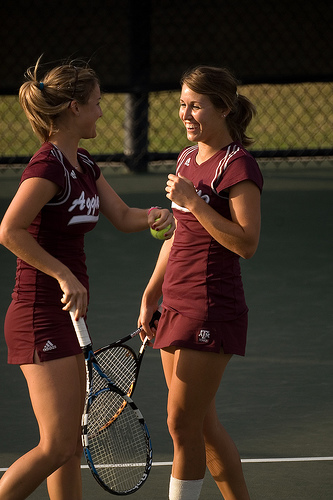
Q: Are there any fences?
A: Yes, there is a fence.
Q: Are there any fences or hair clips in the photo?
A: Yes, there is a fence.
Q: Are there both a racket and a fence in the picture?
A: Yes, there are both a fence and a racket.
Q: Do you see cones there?
A: No, there are no cones.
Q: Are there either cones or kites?
A: No, there are no cones or kites.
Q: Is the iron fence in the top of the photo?
A: Yes, the fence is in the top of the image.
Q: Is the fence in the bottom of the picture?
A: No, the fence is in the top of the image.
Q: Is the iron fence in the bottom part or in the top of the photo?
A: The fence is in the top of the image.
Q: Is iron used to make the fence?
A: Yes, the fence is made of iron.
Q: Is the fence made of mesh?
A: No, the fence is made of iron.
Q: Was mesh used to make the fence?
A: No, the fence is made of iron.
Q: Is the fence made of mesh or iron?
A: The fence is made of iron.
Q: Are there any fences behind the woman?
A: Yes, there is a fence behind the woman.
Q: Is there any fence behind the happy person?
A: Yes, there is a fence behind the woman.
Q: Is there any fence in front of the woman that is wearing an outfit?
A: No, the fence is behind the woman.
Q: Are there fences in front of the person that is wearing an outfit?
A: No, the fence is behind the woman.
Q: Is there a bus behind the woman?
A: No, there is a fence behind the woman.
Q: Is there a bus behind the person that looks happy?
A: No, there is a fence behind the woman.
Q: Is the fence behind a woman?
A: Yes, the fence is behind a woman.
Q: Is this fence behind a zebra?
A: No, the fence is behind a woman.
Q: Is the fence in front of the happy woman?
A: No, the fence is behind the woman.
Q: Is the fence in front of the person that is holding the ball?
A: No, the fence is behind the woman.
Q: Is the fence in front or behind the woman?
A: The fence is behind the woman.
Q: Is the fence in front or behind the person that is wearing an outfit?
A: The fence is behind the woman.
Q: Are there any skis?
A: No, there are no skis.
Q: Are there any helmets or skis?
A: No, there are no skis or helmets.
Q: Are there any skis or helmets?
A: No, there are no skis or helmets.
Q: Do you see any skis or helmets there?
A: No, there are no skis or helmets.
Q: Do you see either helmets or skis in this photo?
A: No, there are no skis or helmets.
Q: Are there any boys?
A: No, there are no boys.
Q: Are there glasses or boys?
A: No, there are no boys or glasses.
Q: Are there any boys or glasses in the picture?
A: No, there are no boys or glasses.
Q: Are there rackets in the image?
A: Yes, there is a racket.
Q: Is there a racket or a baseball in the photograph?
A: Yes, there is a racket.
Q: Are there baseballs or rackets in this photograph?
A: Yes, there is a racket.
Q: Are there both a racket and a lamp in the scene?
A: No, there is a racket but no lamps.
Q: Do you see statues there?
A: No, there are no statues.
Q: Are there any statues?
A: No, there are no statues.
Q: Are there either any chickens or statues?
A: No, there are no statues or chickens.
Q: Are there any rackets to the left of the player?
A: Yes, there is a racket to the left of the player.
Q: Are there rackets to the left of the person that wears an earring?
A: Yes, there is a racket to the left of the player.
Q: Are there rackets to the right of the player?
A: No, the racket is to the left of the player.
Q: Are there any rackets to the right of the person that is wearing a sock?
A: No, the racket is to the left of the player.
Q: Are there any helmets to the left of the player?
A: No, there is a racket to the left of the player.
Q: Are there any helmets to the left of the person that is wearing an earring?
A: No, there is a racket to the left of the player.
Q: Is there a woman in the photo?
A: Yes, there is a woman.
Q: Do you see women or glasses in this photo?
A: Yes, there is a woman.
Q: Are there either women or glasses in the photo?
A: Yes, there is a woman.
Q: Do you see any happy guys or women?
A: Yes, there is a happy woman.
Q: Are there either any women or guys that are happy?
A: Yes, the woman is happy.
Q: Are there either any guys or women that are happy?
A: Yes, the woman is happy.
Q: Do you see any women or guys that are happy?
A: Yes, the woman is happy.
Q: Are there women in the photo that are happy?
A: Yes, there is a happy woman.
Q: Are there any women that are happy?
A: Yes, there is a woman that is happy.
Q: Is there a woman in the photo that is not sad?
A: Yes, there is a happy woman.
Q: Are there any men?
A: No, there are no men.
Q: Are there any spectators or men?
A: No, there are no men or spectators.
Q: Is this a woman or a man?
A: This is a woman.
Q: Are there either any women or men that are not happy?
A: No, there is a woman but she is happy.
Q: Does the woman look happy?
A: Yes, the woman is happy.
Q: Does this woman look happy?
A: Yes, the woman is happy.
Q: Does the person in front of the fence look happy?
A: Yes, the woman is happy.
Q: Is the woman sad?
A: No, the woman is happy.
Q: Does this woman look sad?
A: No, the woman is happy.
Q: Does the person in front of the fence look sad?
A: No, the woman is happy.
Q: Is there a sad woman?
A: No, there is a woman but she is happy.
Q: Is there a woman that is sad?
A: No, there is a woman but she is happy.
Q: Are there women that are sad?
A: No, there is a woman but she is happy.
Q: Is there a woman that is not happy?
A: No, there is a woman but she is happy.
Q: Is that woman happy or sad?
A: The woman is happy.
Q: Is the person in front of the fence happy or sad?
A: The woman is happy.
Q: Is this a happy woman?
A: Yes, this is a happy woman.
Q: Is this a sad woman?
A: No, this is a happy woman.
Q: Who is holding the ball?
A: The woman is holding the ball.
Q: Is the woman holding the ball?
A: Yes, the woman is holding the ball.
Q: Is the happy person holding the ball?
A: Yes, the woman is holding the ball.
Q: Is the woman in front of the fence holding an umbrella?
A: No, the woman is holding the ball.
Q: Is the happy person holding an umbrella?
A: No, the woman is holding the ball.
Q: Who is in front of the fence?
A: The woman is in front of the fence.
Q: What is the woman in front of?
A: The woman is in front of the fence.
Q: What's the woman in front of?
A: The woman is in front of the fence.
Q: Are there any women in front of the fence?
A: Yes, there is a woman in front of the fence.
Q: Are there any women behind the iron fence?
A: No, the woman is in front of the fence.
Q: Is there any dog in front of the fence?
A: No, there is a woman in front of the fence.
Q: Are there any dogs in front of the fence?
A: No, there is a woman in front of the fence.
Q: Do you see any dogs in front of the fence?
A: No, there is a woman in front of the fence.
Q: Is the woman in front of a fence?
A: Yes, the woman is in front of a fence.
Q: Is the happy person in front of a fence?
A: Yes, the woman is in front of a fence.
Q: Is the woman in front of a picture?
A: No, the woman is in front of a fence.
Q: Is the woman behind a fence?
A: No, the woman is in front of a fence.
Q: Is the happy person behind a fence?
A: No, the woman is in front of a fence.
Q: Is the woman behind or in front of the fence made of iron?
A: The woman is in front of the fence.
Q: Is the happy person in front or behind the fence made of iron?
A: The woman is in front of the fence.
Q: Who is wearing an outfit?
A: The woman is wearing an outfit.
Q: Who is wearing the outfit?
A: The woman is wearing an outfit.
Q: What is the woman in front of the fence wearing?
A: The woman is wearing an outfit.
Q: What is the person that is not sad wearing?
A: The woman is wearing an outfit.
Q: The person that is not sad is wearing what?
A: The woman is wearing an outfit.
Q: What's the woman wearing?
A: The woman is wearing an outfit.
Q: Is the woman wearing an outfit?
A: Yes, the woman is wearing an outfit.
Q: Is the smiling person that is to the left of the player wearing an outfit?
A: Yes, the woman is wearing an outfit.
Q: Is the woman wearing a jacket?
A: No, the woman is wearing an outfit.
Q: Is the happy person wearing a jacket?
A: No, the woman is wearing an outfit.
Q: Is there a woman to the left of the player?
A: Yes, there is a woman to the left of the player.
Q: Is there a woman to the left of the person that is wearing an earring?
A: Yes, there is a woman to the left of the player.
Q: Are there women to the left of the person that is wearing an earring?
A: Yes, there is a woman to the left of the player.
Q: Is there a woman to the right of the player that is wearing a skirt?
A: No, the woman is to the left of the player.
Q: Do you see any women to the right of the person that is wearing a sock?
A: No, the woman is to the left of the player.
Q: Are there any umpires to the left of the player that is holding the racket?
A: No, there is a woman to the left of the player.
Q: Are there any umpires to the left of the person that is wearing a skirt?
A: No, there is a woman to the left of the player.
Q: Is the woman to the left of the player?
A: Yes, the woman is to the left of the player.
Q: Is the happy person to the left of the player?
A: Yes, the woman is to the left of the player.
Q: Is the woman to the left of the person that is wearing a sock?
A: Yes, the woman is to the left of the player.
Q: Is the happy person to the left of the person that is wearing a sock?
A: Yes, the woman is to the left of the player.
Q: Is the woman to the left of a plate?
A: No, the woman is to the left of the player.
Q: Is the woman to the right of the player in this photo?
A: No, the woman is to the left of the player.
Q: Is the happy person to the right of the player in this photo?
A: No, the woman is to the left of the player.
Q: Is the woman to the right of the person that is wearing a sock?
A: No, the woman is to the left of the player.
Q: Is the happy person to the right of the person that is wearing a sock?
A: No, the woman is to the left of the player.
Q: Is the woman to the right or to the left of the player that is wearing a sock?
A: The woman is to the left of the player.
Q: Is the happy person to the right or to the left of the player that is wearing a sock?
A: The woman is to the left of the player.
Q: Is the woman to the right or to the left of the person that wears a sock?
A: The woman is to the left of the player.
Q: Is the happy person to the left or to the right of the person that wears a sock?
A: The woman is to the left of the player.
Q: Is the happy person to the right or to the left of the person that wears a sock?
A: The woman is to the left of the player.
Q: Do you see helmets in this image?
A: No, there are no helmets.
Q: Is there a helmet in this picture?
A: No, there are no helmets.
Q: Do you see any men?
A: No, there are no men.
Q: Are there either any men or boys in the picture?
A: No, there are no men or boys.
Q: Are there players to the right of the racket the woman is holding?
A: Yes, there is a player to the right of the racket.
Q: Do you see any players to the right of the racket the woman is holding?
A: Yes, there is a player to the right of the racket.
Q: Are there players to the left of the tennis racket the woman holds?
A: No, the player is to the right of the tennis racket.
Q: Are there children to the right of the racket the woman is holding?
A: No, there is a player to the right of the tennis racket.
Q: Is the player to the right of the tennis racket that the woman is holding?
A: Yes, the player is to the right of the racket.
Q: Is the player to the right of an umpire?
A: No, the player is to the right of the racket.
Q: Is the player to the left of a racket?
A: No, the player is to the right of a racket.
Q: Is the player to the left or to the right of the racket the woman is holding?
A: The player is to the right of the racket.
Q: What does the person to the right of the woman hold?
A: The player holds the tennis racket.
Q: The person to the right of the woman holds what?
A: The player holds the tennis racket.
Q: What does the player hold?
A: The player holds the tennis racket.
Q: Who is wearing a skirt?
A: The player is wearing a skirt.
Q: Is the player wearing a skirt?
A: Yes, the player is wearing a skirt.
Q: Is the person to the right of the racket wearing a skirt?
A: Yes, the player is wearing a skirt.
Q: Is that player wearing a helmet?
A: No, the player is wearing a skirt.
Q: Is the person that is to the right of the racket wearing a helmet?
A: No, the player is wearing a skirt.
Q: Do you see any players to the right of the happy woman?
A: Yes, there is a player to the right of the woman.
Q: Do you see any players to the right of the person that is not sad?
A: Yes, there is a player to the right of the woman.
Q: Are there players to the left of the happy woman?
A: No, the player is to the right of the woman.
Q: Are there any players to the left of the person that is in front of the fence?
A: No, the player is to the right of the woman.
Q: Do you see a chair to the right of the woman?
A: No, there is a player to the right of the woman.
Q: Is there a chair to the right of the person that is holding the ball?
A: No, there is a player to the right of the woman.